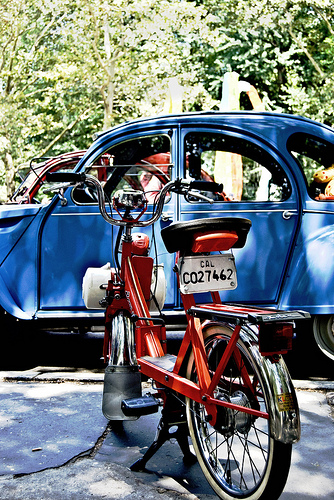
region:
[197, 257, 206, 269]
The letter is black.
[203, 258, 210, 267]
The letter is black.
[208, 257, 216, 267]
The letter is black.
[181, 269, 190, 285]
The letter is black.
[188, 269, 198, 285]
The number is black.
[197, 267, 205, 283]
The number is black.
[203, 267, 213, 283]
The number is black.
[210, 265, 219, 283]
The number is black.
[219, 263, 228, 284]
The number is black.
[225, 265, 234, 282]
The number is black.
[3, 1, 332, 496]
it is daytime outside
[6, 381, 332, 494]
the ground has gaps and cracks in it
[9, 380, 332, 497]
the ground is gray in color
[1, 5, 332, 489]
it is very sunny outside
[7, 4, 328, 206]
trees are around the area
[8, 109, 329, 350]
a car is near the trees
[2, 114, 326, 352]
the car is a blue car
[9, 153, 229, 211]
a red car is beside the blue car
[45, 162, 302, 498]
a red bike is near the blue car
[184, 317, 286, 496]
the back wheel of the bike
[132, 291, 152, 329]
the scooter is red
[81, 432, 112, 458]
the sidewalk has a crack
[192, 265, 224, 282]
the tag is white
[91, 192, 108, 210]
the handle is silver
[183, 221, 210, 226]
the seat is black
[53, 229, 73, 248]
the bug is blue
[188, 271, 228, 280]
the numbers are balck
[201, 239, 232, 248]
the cover is red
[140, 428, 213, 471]
the scooter has a stand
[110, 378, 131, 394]
the mud flap is black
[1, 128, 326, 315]
the car is parked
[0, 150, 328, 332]
the car is blue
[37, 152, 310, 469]
the bike is parked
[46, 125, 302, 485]
the bike is red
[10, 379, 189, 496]
the sidewalk is cracked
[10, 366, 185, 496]
shadow on the sidewalk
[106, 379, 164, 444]
the pedals are black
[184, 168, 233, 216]
the handles are black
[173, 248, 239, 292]
license plate on back of bike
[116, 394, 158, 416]
black hard plastic bike pedal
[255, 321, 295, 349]
light on back of bike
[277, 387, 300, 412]
yellow sticker on back of bike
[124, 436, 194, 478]
black metal bike kickstand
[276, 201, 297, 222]
silver metal car door handle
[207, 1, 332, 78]
trees covered in green leaves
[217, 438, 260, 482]
silver wheel spokes on bike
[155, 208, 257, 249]
black seat on bike